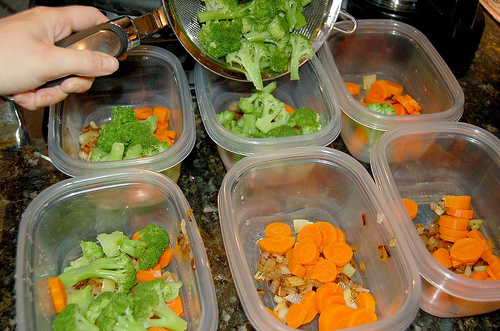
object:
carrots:
[323, 243, 356, 265]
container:
[219, 146, 422, 329]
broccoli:
[130, 280, 189, 330]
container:
[13, 168, 220, 330]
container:
[372, 121, 499, 319]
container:
[316, 16, 468, 163]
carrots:
[395, 94, 415, 113]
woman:
[2, 2, 120, 110]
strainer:
[56, 0, 359, 82]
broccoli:
[227, 40, 289, 91]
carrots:
[133, 263, 166, 281]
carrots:
[159, 124, 176, 141]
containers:
[215, 147, 419, 331]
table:
[467, 11, 499, 124]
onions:
[283, 273, 309, 288]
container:
[45, 44, 198, 209]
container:
[194, 39, 345, 187]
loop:
[332, 7, 356, 40]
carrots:
[285, 100, 299, 115]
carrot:
[293, 239, 317, 266]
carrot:
[48, 278, 65, 314]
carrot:
[450, 237, 481, 262]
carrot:
[155, 107, 171, 128]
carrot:
[346, 76, 362, 98]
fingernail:
[103, 52, 121, 73]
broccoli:
[127, 119, 158, 161]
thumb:
[52, 45, 122, 81]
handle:
[51, 8, 169, 72]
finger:
[48, 5, 107, 34]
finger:
[12, 95, 34, 111]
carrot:
[134, 104, 151, 123]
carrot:
[444, 194, 474, 210]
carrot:
[400, 197, 420, 219]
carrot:
[266, 221, 291, 243]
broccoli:
[123, 223, 170, 270]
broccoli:
[59, 253, 136, 292]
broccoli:
[52, 303, 96, 331]